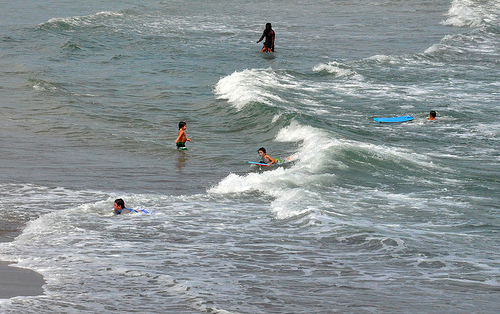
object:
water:
[22, 63, 90, 130]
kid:
[257, 147, 295, 166]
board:
[372, 115, 414, 123]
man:
[256, 23, 275, 53]